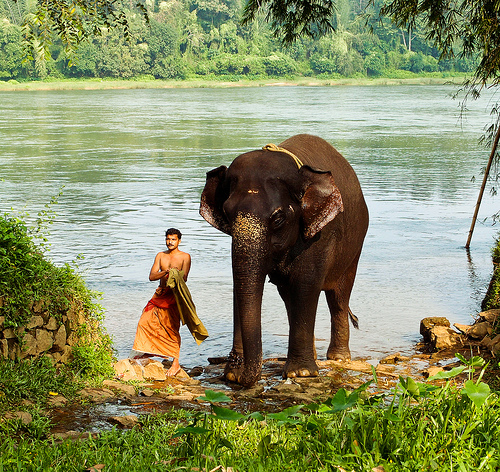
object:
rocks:
[108, 413, 140, 427]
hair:
[164, 227, 182, 238]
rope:
[261, 142, 303, 169]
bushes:
[144, 18, 189, 81]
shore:
[0, 77, 498, 89]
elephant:
[198, 134, 368, 390]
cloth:
[132, 286, 182, 358]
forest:
[0, 0, 499, 82]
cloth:
[167, 268, 209, 345]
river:
[0, 86, 499, 435]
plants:
[27, 183, 67, 253]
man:
[132, 227, 191, 377]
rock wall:
[0, 297, 82, 370]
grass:
[169, 388, 243, 470]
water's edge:
[0, 379, 496, 451]